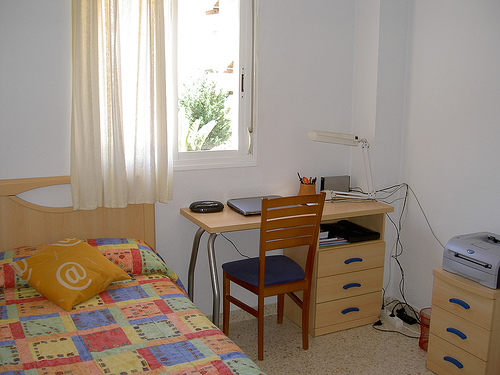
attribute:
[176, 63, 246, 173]
plant — green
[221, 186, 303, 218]
laptop — computer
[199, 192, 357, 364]
chair — brown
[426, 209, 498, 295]
printer — gray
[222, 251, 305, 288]
cushion — blue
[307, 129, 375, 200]
lamp — white, desk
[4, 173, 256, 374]
bed — neatly made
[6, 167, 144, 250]
headboard — tan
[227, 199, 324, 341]
chair — dark wood